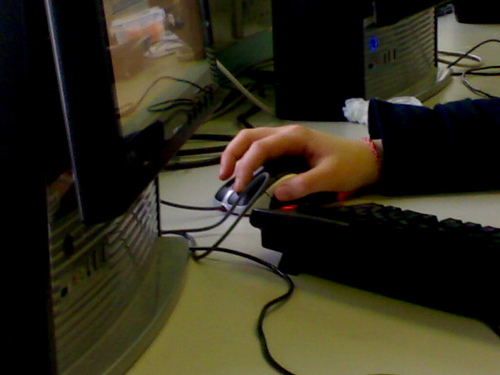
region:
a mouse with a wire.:
[209, 149, 331, 374]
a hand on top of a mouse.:
[207, 113, 375, 218]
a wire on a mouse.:
[144, 192, 316, 374]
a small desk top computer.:
[4, 3, 135, 229]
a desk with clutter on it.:
[11, 0, 496, 368]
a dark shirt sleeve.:
[366, 82, 498, 200]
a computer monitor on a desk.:
[35, 2, 255, 242]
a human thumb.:
[261, 172, 303, 216]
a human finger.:
[224, 133, 267, 210]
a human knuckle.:
[276, 108, 306, 150]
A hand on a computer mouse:
[219, 131, 390, 212]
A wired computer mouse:
[213, 166, 298, 213]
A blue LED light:
[367, 35, 379, 51]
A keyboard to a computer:
[251, 204, 497, 311]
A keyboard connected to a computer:
[248, 201, 496, 309]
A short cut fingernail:
[218, 167, 227, 177]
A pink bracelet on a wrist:
[368, 138, 381, 180]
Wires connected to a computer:
[433, 35, 498, 96]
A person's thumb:
[273, 164, 351, 196]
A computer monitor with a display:
[43, 1, 224, 220]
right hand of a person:
[217, 125, 382, 202]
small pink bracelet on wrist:
[360, 133, 378, 177]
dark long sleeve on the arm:
[367, 98, 498, 195]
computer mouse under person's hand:
[213, 161, 343, 213]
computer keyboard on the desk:
[249, 206, 498, 319]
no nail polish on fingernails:
[216, 163, 293, 200]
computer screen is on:
[37, 0, 219, 222]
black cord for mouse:
[160, 174, 316, 374]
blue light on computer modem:
[366, 33, 380, 52]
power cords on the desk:
[439, 37, 498, 97]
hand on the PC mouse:
[222, 124, 392, 204]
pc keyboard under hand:
[257, 183, 498, 308]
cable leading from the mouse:
[184, 236, 296, 371]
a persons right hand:
[220, 124, 412, 204]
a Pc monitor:
[42, 1, 220, 231]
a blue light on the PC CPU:
[365, 38, 387, 60]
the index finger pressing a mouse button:
[236, 126, 306, 190]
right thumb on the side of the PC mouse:
[279, 160, 392, 205]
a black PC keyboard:
[249, 184, 498, 311]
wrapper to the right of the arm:
[340, 90, 420, 122]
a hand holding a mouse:
[217, 121, 363, 218]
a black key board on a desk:
[260, 190, 496, 299]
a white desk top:
[203, 261, 367, 370]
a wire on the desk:
[227, 266, 329, 353]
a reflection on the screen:
[127, 2, 236, 134]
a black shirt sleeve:
[383, 131, 493, 196]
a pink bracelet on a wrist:
[353, 132, 391, 177]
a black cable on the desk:
[164, 107, 254, 177]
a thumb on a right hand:
[273, 158, 327, 218]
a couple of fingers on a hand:
[211, 120, 299, 203]